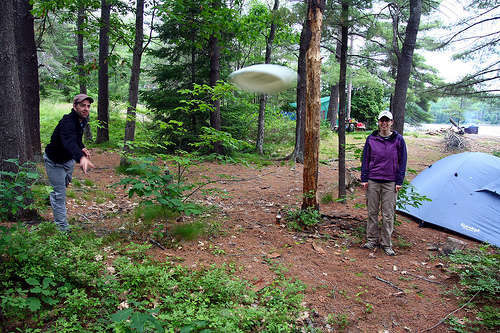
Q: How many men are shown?
A: Two.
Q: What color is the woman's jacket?
A: Purple.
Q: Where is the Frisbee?
A: In the air.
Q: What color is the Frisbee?
A: White.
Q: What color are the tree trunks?
A: Brown.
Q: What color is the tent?
A: Blue.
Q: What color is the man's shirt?
A: Black.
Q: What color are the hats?
A: Tan.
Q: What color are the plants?
A: Green.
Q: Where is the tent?
A: Behind the woman.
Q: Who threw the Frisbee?
A: The man on the left.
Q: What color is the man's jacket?
A: Navy blue.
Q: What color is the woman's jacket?
A: Purple.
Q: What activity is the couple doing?
A: Frisbee.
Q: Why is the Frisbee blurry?
A: It's flying.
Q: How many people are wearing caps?
A: 2.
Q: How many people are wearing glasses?
A: 1.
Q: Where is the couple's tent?
A: On the right.